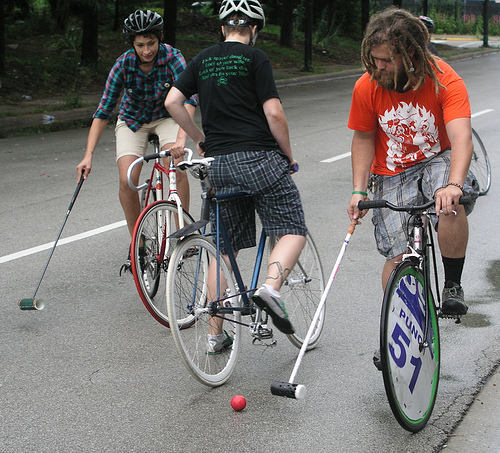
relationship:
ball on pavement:
[229, 387, 249, 413] [4, 61, 497, 447]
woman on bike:
[91, 21, 185, 176] [90, 137, 244, 311]